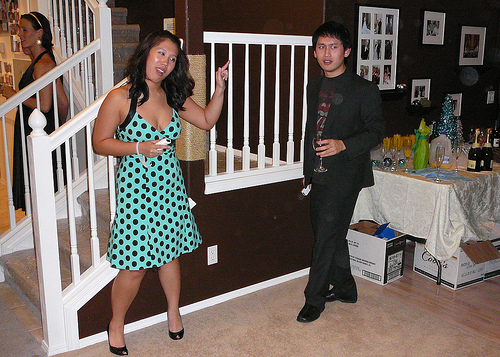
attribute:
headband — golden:
[11, 0, 63, 25]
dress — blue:
[106, 82, 203, 272]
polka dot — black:
[171, 201, 176, 206]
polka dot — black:
[170, 236, 176, 241]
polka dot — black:
[134, 177, 141, 184]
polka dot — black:
[126, 222, 130, 230]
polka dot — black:
[169, 126, 175, 131]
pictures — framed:
[356, 7, 399, 92]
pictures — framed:
[422, 5, 448, 47]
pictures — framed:
[412, 75, 433, 105]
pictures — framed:
[457, 20, 490, 74]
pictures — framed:
[439, 91, 466, 121]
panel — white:
[203, 241, 219, 267]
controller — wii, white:
[134, 132, 174, 169]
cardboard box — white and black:
[342, 218, 408, 286]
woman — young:
[92, 27, 229, 354]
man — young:
[294, 27, 379, 327]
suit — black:
[298, 66, 385, 327]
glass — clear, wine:
[312, 130, 327, 172]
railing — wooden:
[18, 106, 140, 313]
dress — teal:
[108, 108, 201, 268]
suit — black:
[303, 66, 384, 308]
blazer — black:
[278, 70, 385, 222]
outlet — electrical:
[195, 219, 227, 293]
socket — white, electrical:
[205, 243, 220, 267]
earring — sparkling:
[33, 38, 43, 47]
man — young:
[273, 20, 373, 321]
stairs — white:
[29, 9, 282, 282]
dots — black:
[138, 177, 177, 227]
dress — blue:
[89, 100, 216, 260]